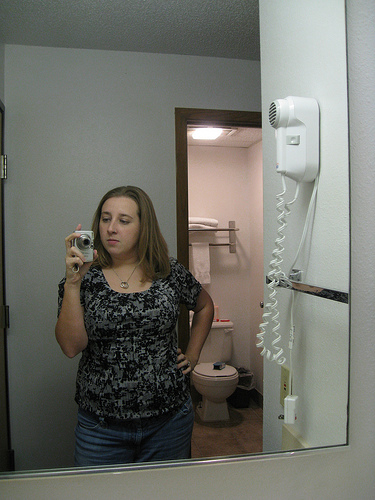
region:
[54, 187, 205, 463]
a woman standing and taking a selfie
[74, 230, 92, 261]
the woman's camera in her hand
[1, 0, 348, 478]
the mirror on the wall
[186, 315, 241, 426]
the toilet in the bathroom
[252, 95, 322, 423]
a fancy hair dryer attached to the wall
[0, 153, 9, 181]
the hinge on the door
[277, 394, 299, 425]
the plug hanging from the cord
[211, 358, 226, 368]
a box on the toilet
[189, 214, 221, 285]
some towels on the rack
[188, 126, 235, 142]
a light above the toilet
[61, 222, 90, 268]
A white camera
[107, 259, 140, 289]
a silver necklace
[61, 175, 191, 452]
A woman taking a picture in the mirror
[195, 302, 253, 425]
A toilet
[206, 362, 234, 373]
box resting on toilet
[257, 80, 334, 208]
A hair dryer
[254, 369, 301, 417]
an electrical outlet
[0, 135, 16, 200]
A door hinge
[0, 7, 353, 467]
A mirror hanging on the wall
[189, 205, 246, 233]
towels resting on a rack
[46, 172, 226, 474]
A woman taking a selfie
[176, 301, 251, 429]
A toilet in the bathroom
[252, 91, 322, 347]
A hair dryer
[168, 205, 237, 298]
Towels lay in the bathroom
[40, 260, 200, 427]
She is wearing a black and grey shirt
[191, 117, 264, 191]
The light is on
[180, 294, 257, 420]
The toilet is white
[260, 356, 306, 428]
The cord is unplugged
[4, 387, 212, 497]
She is wearing jeans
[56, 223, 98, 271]
A digital camera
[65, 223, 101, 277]
A SILVER CAMERA TAKING A PICTURE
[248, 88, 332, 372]
A WALL MOUNTED HAIR DRYER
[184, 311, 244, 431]
A WHITE TOILET WITH THE LID CLOSED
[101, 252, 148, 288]
A NECKLACE AROUND A WOMAN'S NECK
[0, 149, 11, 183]
THE SILVER HINGE OF A DOOR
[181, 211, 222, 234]
TWO FOLDED TOWELS ON A TOWEL RACK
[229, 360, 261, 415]
A TRASHCAN WITH A PLASTIC LINER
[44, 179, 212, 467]
A WOMAN TAKING A PHOTO OF HERSELF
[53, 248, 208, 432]
A BLACK, WHITE, AND GRAY BLOUSE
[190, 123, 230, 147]
A FLORESCENT LIGHT IN THE BATHROOM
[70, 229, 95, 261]
Small white and gray camera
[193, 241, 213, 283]
White towel hanging on the towel rack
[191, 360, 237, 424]
Middle and bottom section of white toilet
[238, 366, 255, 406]
Black garbage pail in bathroom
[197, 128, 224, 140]
Bright light in bathroom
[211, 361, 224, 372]
An empty soap box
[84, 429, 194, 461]
Blue jeans of female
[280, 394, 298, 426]
A white outlet plug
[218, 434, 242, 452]
Brown tiled floor in bathroom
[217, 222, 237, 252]
Part of a silver towel rack